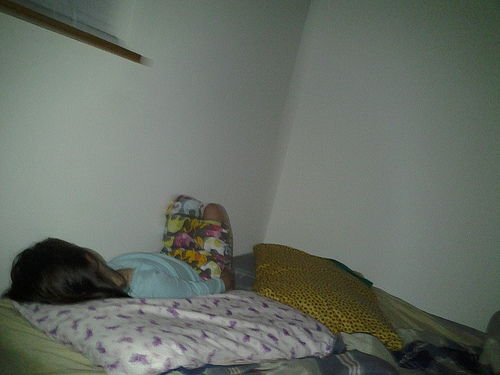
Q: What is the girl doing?
A: Lying down.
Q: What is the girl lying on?
A: A bed.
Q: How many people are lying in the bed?
A: One.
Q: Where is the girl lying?
A: On top of a bed.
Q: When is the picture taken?
A: At bedtime.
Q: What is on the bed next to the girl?
A: A pillow.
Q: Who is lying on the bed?
A: A girl.